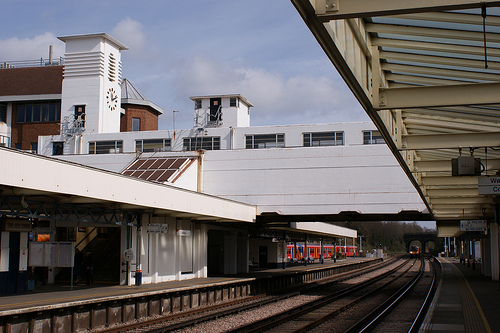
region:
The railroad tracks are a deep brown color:
[318, 301, 333, 326]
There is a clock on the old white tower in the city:
[103, 81, 123, 112]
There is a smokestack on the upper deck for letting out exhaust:
[46, 45, 56, 82]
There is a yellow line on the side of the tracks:
[466, 296, 482, 331]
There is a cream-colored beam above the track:
[415, 92, 431, 107]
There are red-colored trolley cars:
[291, 242, 309, 262]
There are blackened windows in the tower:
[30, 108, 44, 124]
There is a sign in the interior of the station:
[8, 221, 33, 236]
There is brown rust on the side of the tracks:
[203, 294, 212, 304]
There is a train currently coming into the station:
[408, 243, 422, 260]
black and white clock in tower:
[101, 82, 124, 112]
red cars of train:
[288, 238, 363, 255]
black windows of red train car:
[303, 242, 319, 263]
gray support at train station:
[317, 5, 492, 155]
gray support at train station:
[386, 113, 499, 208]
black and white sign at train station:
[454, 152, 487, 189]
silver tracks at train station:
[395, 261, 426, 331]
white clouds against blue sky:
[136, 12, 296, 82]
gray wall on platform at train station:
[132, 220, 212, 275]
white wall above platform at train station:
[231, 147, 391, 205]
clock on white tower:
[99, 86, 119, 120]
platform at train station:
[86, 267, 241, 309]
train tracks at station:
[368, 265, 440, 325]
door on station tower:
[68, 100, 89, 132]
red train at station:
[277, 240, 364, 263]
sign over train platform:
[448, 214, 486, 239]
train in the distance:
[405, 241, 425, 263]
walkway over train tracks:
[257, 131, 380, 212]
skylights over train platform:
[404, 19, 487, 77]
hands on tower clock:
[106, 91, 120, 106]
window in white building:
[243, 121, 318, 160]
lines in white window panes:
[244, 126, 287, 153]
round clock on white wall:
[96, 76, 138, 125]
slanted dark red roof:
[127, 139, 192, 204]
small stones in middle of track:
[220, 302, 300, 319]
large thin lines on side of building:
[209, 156, 403, 198]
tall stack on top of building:
[33, 36, 62, 76]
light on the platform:
[22, 219, 73, 247]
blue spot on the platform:
[281, 236, 327, 266]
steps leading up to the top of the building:
[175, 83, 247, 136]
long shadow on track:
[274, 256, 363, 324]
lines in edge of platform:
[128, 301, 200, 313]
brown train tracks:
[167, 303, 244, 330]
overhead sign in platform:
[435, 141, 499, 194]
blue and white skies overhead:
[125, 41, 260, 82]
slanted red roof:
[118, 151, 201, 205]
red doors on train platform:
[270, 229, 377, 271]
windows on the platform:
[28, 219, 103, 252]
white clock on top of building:
[101, 63, 138, 120]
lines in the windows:
[240, 114, 300, 156]